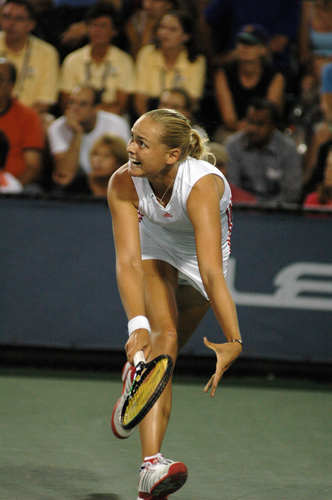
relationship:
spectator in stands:
[216, 98, 309, 207] [3, 4, 329, 232]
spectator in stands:
[53, 88, 130, 176] [3, 4, 329, 232]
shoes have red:
[92, 361, 190, 491] [155, 466, 191, 489]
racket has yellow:
[93, 339, 185, 430] [122, 374, 164, 405]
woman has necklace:
[73, 103, 256, 495] [143, 176, 182, 209]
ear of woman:
[164, 141, 185, 168] [73, 103, 256, 495]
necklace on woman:
[143, 176, 182, 209] [73, 103, 256, 495]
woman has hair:
[73, 103, 256, 495] [129, 97, 218, 184]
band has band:
[128, 315, 152, 336] [128, 315, 152, 336]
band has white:
[127, 317, 150, 330] [128, 320, 140, 329]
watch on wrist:
[225, 337, 246, 347] [210, 315, 251, 360]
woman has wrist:
[73, 103, 256, 495] [114, 306, 155, 348]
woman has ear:
[73, 103, 256, 495] [164, 141, 185, 168]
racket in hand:
[93, 339, 185, 430] [121, 338, 154, 358]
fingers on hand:
[204, 369, 227, 398] [200, 336, 244, 391]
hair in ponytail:
[129, 97, 218, 184] [181, 120, 223, 173]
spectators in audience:
[19, 22, 151, 162] [25, 18, 296, 169]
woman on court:
[73, 103, 256, 495] [10, 350, 324, 499]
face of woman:
[116, 114, 170, 180] [73, 103, 256, 495]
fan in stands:
[68, 4, 130, 96] [3, 4, 329, 232]